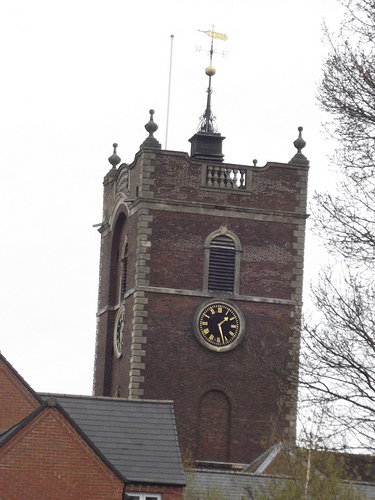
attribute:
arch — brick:
[191, 384, 237, 467]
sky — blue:
[23, 58, 76, 107]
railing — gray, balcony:
[201, 161, 252, 207]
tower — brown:
[76, 18, 331, 338]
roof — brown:
[42, 394, 184, 482]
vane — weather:
[193, 25, 243, 111]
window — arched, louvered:
[200, 224, 243, 292]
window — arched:
[200, 220, 250, 295]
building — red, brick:
[1, 353, 192, 498]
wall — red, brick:
[239, 326, 291, 405]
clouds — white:
[35, 26, 346, 156]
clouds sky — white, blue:
[76, 25, 133, 83]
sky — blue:
[37, 192, 79, 264]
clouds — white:
[16, 177, 87, 294]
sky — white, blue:
[0, 10, 373, 451]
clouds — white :
[232, 34, 306, 117]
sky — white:
[29, 21, 145, 90]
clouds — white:
[234, 43, 280, 99]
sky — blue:
[27, 27, 125, 119]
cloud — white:
[5, 2, 374, 452]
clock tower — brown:
[102, 129, 307, 441]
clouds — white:
[2, 6, 102, 207]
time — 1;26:
[192, 297, 245, 351]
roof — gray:
[26, 390, 189, 486]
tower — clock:
[86, 68, 309, 471]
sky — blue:
[8, 14, 363, 365]